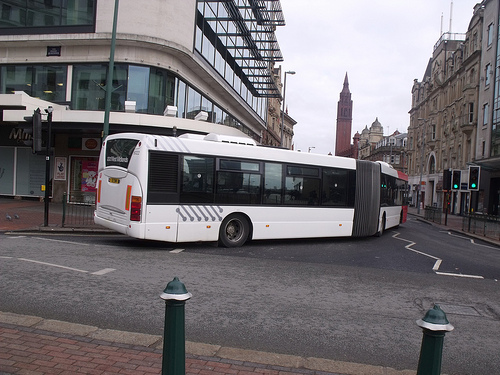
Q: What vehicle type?
A: Bus.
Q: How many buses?
A: One.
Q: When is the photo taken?
A: Daytime.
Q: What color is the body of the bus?
A: White.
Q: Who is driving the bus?
A: Bus driver.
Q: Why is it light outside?
A: Sunshine.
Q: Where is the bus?
A: Street.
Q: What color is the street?
A: Gray.